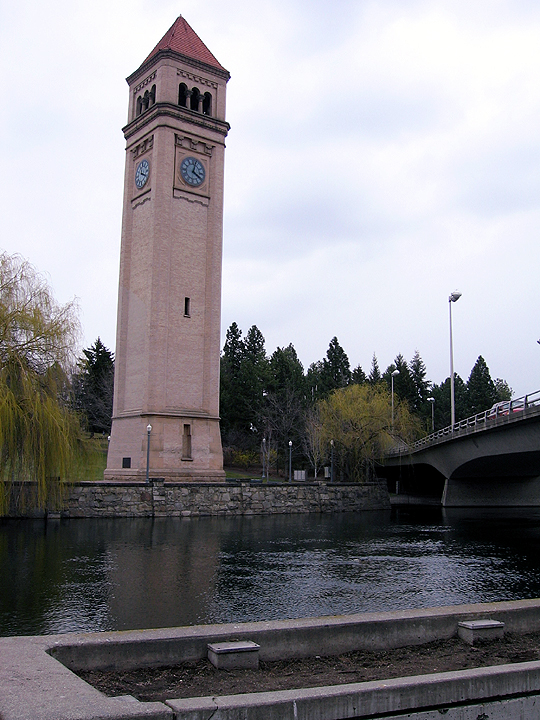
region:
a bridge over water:
[377, 386, 537, 523]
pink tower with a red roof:
[104, 7, 239, 489]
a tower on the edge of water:
[106, 9, 236, 484]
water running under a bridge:
[5, 515, 537, 601]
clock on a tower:
[171, 138, 211, 200]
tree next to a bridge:
[308, 381, 426, 489]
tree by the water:
[1, 245, 85, 523]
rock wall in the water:
[8, 476, 399, 519]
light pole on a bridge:
[443, 287, 463, 428]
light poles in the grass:
[258, 431, 339, 484]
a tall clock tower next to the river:
[101, 14, 230, 483]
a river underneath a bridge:
[0, 504, 539, 635]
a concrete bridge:
[380, 389, 537, 508]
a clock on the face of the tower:
[178, 155, 206, 187]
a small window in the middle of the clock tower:
[184, 299, 190, 315]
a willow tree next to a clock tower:
[1, 251, 102, 519]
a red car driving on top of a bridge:
[488, 400, 532, 416]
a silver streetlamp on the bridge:
[448, 293, 461, 429]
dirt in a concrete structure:
[65, 631, 537, 702]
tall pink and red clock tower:
[98, 2, 248, 478]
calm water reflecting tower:
[99, 522, 264, 580]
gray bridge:
[411, 396, 539, 485]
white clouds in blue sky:
[50, 184, 77, 222]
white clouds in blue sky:
[465, 284, 506, 358]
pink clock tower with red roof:
[109, 10, 233, 492]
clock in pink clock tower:
[177, 146, 220, 196]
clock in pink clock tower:
[128, 139, 168, 196]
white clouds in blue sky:
[317, 73, 366, 110]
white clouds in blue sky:
[237, 184, 320, 295]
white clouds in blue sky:
[350, 246, 408, 307]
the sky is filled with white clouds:
[434, 203, 535, 265]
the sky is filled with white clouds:
[420, 124, 531, 193]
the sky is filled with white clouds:
[416, 7, 539, 84]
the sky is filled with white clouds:
[276, 182, 404, 262]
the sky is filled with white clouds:
[320, 115, 428, 171]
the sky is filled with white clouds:
[341, 8, 445, 79]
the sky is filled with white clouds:
[237, 234, 325, 313]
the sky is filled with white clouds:
[235, 83, 352, 179]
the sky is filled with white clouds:
[241, 1, 345, 82]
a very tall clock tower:
[91, 1, 255, 487]